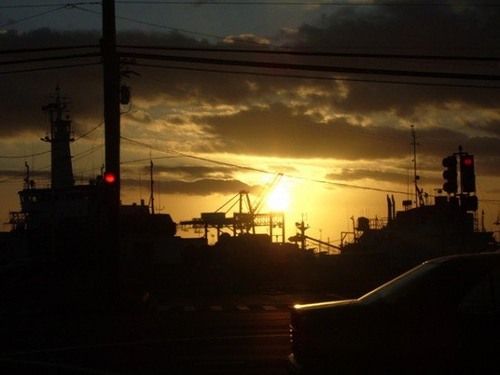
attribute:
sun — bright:
[260, 174, 309, 214]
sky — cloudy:
[13, 20, 491, 171]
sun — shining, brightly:
[253, 155, 313, 205]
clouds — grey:
[202, 52, 307, 81]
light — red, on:
[97, 168, 121, 202]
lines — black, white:
[196, 286, 302, 321]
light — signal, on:
[434, 145, 488, 209]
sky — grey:
[267, 80, 363, 158]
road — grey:
[209, 317, 273, 351]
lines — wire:
[157, 29, 368, 101]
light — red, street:
[436, 139, 485, 215]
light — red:
[95, 162, 123, 185]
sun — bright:
[173, 92, 358, 277]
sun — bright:
[253, 152, 302, 216]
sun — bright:
[257, 159, 297, 225]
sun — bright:
[258, 160, 300, 220]